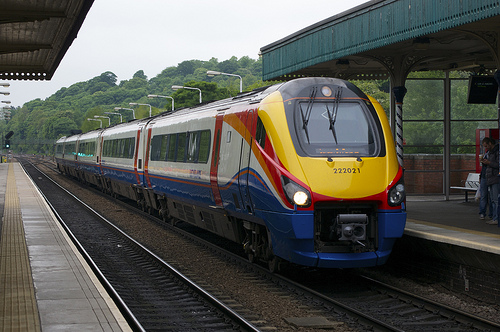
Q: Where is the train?
A: On the track.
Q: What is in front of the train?
A: The track.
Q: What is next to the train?
A: A track.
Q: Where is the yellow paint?
A: On the front of the train.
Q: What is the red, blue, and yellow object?
A: A high speed public train.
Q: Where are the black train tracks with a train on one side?
A: At a train station.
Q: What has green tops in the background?
A: Trees.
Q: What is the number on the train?
A: 222021.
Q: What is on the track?
A: A train.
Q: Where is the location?
A: Train station.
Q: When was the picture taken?
A: Day time.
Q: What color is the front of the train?
A: Yellow.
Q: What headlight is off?
A: The right.